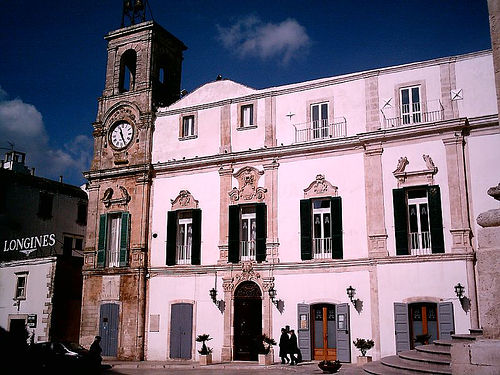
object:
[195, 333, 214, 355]
plant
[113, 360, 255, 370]
sidewalk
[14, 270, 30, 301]
window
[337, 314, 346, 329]
window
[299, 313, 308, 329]
window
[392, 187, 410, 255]
shutter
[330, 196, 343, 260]
shutter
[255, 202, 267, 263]
shutter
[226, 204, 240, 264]
shutter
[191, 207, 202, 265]
shutter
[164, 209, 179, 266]
shutter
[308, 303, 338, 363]
door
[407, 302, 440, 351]
door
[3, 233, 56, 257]
sign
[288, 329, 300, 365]
people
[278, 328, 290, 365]
people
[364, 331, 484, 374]
staircase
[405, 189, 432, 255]
window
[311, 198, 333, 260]
window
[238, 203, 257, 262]
window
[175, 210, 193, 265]
window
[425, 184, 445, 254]
shutter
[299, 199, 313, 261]
shutter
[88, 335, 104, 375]
man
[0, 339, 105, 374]
car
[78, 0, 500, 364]
building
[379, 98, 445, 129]
balcony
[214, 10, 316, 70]
cloud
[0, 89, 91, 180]
cloud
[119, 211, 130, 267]
green shutter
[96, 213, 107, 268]
green shutter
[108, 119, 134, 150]
clock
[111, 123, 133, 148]
face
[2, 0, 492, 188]
sky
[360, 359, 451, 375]
step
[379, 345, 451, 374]
step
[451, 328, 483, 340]
step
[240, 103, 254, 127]
window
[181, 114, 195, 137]
window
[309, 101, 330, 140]
window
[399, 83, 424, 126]
window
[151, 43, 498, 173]
floor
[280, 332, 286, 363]
black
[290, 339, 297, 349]
black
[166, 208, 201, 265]
black shutter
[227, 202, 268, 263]
black shutter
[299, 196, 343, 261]
black shutter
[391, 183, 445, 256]
black shutter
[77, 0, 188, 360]
tower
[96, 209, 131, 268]
window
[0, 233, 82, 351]
building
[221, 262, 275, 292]
scrollwork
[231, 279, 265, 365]
doorway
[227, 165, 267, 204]
scrollwork